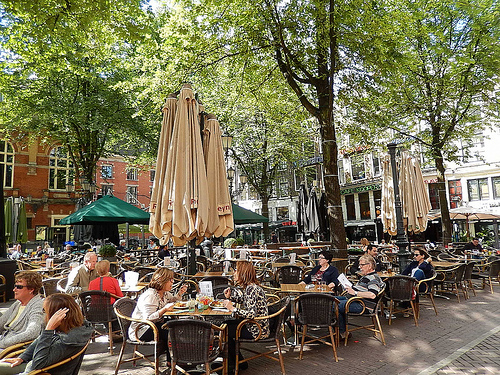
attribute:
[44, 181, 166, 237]
canopy — green, triangular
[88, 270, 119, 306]
shirt — red 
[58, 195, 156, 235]
canopy — green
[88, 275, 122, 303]
shirt — red 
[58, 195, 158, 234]
tent — green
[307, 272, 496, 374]
patio — brick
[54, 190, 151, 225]
canopy — green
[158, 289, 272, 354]
table — reading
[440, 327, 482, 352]
path — brick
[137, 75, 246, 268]
umbrella — closed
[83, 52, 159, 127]
leaves — green